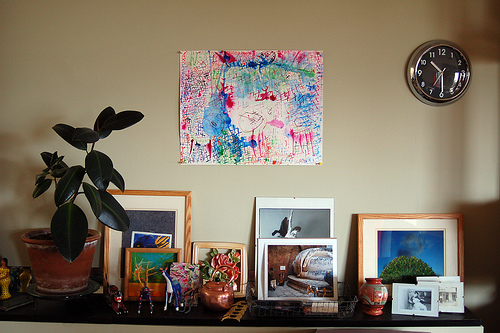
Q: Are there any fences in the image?
A: No, there are no fences.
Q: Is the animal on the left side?
A: Yes, the animal is on the left of the image.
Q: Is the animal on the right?
A: No, the animal is on the left of the image.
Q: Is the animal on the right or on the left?
A: The animal is on the left of the image.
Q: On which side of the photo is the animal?
A: The animal is on the left of the image.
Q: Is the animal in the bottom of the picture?
A: Yes, the animal is in the bottom of the image.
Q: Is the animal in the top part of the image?
A: No, the animal is in the bottom of the image.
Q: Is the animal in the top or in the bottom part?
A: The animal is in the bottom of the image.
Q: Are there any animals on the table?
A: Yes, there is an animal on the table.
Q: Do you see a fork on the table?
A: No, there is an animal on the table.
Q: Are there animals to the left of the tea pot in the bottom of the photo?
A: Yes, there is an animal to the left of the tea pot.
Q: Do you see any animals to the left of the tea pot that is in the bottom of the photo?
A: Yes, there is an animal to the left of the tea pot.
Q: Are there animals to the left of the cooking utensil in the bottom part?
A: Yes, there is an animal to the left of the tea pot.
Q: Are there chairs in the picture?
A: No, there are no chairs.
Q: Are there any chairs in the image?
A: No, there are no chairs.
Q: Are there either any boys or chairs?
A: No, there are no chairs or boys.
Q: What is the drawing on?
A: The drawing is on the wall.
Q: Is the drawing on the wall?
A: Yes, the drawing is on the wall.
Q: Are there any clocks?
A: Yes, there is a clock.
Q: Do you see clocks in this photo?
A: Yes, there is a clock.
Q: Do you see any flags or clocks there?
A: Yes, there is a clock.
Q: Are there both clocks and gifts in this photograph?
A: No, there is a clock but no gifts.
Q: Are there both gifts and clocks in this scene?
A: No, there is a clock but no gifts.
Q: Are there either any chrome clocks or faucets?
A: Yes, there is a chrome clock.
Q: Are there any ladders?
A: No, there are no ladders.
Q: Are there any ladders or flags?
A: No, there are no ladders or flags.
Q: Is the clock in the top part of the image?
A: Yes, the clock is in the top of the image.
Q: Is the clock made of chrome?
A: Yes, the clock is made of chrome.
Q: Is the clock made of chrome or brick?
A: The clock is made of chrome.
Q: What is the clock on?
A: The clock is on the wall.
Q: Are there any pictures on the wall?
A: No, there is a clock on the wall.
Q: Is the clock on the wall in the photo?
A: Yes, the clock is on the wall.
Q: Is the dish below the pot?
A: Yes, the dish is below the pot.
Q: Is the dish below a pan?
A: No, the dish is below the pot.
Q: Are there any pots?
A: Yes, there is a pot.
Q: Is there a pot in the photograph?
A: Yes, there is a pot.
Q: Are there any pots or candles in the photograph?
A: Yes, there is a pot.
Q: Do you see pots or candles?
A: Yes, there is a pot.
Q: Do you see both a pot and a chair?
A: No, there is a pot but no chairs.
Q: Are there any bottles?
A: No, there are no bottles.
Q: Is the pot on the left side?
A: Yes, the pot is on the left of the image.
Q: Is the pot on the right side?
A: No, the pot is on the left of the image.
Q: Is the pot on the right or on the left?
A: The pot is on the left of the image.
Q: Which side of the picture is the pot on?
A: The pot is on the left of the image.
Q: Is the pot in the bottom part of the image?
A: Yes, the pot is in the bottom of the image.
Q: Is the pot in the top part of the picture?
A: No, the pot is in the bottom of the image.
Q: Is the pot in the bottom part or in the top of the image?
A: The pot is in the bottom of the image.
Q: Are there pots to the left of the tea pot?
A: Yes, there is a pot to the left of the tea pot.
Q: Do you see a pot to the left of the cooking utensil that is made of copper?
A: Yes, there is a pot to the left of the tea pot.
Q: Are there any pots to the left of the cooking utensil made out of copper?
A: Yes, there is a pot to the left of the tea pot.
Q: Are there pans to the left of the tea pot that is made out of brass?
A: No, there is a pot to the left of the tea pot.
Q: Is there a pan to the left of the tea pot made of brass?
A: No, there is a pot to the left of the tea pot.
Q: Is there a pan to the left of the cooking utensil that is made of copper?
A: No, there is a pot to the left of the tea pot.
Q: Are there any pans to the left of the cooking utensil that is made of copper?
A: No, there is a pot to the left of the tea pot.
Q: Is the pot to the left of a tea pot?
A: Yes, the pot is to the left of a tea pot.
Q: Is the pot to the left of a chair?
A: No, the pot is to the left of a tea pot.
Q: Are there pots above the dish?
A: Yes, there is a pot above the dish.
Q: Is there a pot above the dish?
A: Yes, there is a pot above the dish.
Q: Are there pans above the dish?
A: No, there is a pot above the dish.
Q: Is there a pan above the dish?
A: No, there is a pot above the dish.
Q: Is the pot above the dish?
A: Yes, the pot is above the dish.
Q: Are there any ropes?
A: No, there are no ropes.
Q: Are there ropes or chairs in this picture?
A: No, there are no ropes or chairs.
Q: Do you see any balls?
A: No, there are no balls.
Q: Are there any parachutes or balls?
A: No, there are no balls or parachutes.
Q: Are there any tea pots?
A: Yes, there is a tea pot.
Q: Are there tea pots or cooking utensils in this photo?
A: Yes, there is a tea pot.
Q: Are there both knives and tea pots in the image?
A: No, there is a tea pot but no knives.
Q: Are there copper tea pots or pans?
A: Yes, there is a copper tea pot.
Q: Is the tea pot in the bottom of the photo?
A: Yes, the tea pot is in the bottom of the image.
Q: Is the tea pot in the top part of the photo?
A: No, the tea pot is in the bottom of the image.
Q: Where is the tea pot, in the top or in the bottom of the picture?
A: The tea pot is in the bottom of the image.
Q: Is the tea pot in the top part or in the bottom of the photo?
A: The tea pot is in the bottom of the image.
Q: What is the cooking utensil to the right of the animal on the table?
A: The cooking utensil is a tea pot.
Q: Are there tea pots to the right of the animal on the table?
A: Yes, there is a tea pot to the right of the animal.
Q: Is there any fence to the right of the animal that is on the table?
A: No, there is a tea pot to the right of the animal.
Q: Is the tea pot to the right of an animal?
A: Yes, the tea pot is to the right of an animal.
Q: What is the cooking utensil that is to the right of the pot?
A: The cooking utensil is a tea pot.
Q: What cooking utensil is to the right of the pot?
A: The cooking utensil is a tea pot.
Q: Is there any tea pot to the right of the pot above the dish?
A: Yes, there is a tea pot to the right of the pot.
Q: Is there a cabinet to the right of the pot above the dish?
A: No, there is a tea pot to the right of the pot.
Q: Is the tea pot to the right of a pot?
A: Yes, the tea pot is to the right of a pot.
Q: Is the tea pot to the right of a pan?
A: No, the tea pot is to the right of a pot.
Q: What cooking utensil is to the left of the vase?
A: The cooking utensil is a tea pot.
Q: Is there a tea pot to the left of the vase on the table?
A: Yes, there is a tea pot to the left of the vase.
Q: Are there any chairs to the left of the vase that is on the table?
A: No, there is a tea pot to the left of the vase.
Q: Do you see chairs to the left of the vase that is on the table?
A: No, there is a tea pot to the left of the vase.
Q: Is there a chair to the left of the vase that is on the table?
A: No, there is a tea pot to the left of the vase.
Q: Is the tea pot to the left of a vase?
A: Yes, the tea pot is to the left of a vase.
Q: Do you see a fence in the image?
A: No, there are no fences.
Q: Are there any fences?
A: No, there are no fences.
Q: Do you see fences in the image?
A: No, there are no fences.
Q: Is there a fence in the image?
A: No, there are no fences.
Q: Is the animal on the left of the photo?
A: Yes, the animal is on the left of the image.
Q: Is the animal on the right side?
A: No, the animal is on the left of the image.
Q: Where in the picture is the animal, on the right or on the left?
A: The animal is on the left of the image.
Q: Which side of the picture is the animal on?
A: The animal is on the left of the image.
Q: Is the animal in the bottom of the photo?
A: Yes, the animal is in the bottom of the image.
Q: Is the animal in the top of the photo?
A: No, the animal is in the bottom of the image.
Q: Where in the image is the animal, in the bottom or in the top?
A: The animal is in the bottom of the image.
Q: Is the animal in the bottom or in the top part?
A: The animal is in the bottom of the image.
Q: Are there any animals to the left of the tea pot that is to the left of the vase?
A: Yes, there is an animal to the left of the tea pot.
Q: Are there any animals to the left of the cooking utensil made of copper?
A: Yes, there is an animal to the left of the tea pot.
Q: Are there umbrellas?
A: No, there are no umbrellas.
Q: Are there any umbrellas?
A: No, there are no umbrellas.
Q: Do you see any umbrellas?
A: No, there are no umbrellas.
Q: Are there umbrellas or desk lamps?
A: No, there are no umbrellas or desk lamps.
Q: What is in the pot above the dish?
A: The plant is in the pot.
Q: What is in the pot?
A: The plant is in the pot.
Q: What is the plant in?
A: The plant is in the pot.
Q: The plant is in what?
A: The plant is in the pot.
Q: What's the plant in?
A: The plant is in the pot.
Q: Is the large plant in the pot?
A: Yes, the plant is in the pot.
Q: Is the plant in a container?
A: No, the plant is in the pot.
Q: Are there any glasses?
A: No, there are no glasses.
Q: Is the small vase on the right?
A: Yes, the vase is on the right of the image.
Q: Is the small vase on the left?
A: No, the vase is on the right of the image.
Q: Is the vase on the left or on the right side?
A: The vase is on the right of the image.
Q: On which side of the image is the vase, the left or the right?
A: The vase is on the right of the image.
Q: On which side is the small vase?
A: The vase is on the right of the image.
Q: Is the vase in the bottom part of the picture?
A: Yes, the vase is in the bottom of the image.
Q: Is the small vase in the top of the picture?
A: No, the vase is in the bottom of the image.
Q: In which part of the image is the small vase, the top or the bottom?
A: The vase is in the bottom of the image.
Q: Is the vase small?
A: Yes, the vase is small.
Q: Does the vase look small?
A: Yes, the vase is small.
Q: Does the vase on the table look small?
A: Yes, the vase is small.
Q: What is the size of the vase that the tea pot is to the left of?
A: The vase is small.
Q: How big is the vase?
A: The vase is small.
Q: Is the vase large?
A: No, the vase is small.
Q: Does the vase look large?
A: No, the vase is small.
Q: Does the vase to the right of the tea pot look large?
A: No, the vase is small.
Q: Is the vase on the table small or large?
A: The vase is small.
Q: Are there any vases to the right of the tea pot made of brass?
A: Yes, there is a vase to the right of the tea pot.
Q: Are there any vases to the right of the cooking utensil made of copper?
A: Yes, there is a vase to the right of the tea pot.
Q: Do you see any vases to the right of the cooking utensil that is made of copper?
A: Yes, there is a vase to the right of the tea pot.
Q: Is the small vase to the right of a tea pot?
A: Yes, the vase is to the right of a tea pot.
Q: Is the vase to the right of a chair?
A: No, the vase is to the right of a tea pot.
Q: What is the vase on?
A: The vase is on the table.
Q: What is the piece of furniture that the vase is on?
A: The piece of furniture is a table.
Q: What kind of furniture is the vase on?
A: The vase is on the table.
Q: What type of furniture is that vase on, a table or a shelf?
A: The vase is on a table.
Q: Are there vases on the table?
A: Yes, there is a vase on the table.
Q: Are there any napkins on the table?
A: No, there is a vase on the table.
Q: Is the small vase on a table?
A: Yes, the vase is on a table.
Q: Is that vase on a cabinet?
A: No, the vase is on a table.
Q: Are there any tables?
A: Yes, there is a table.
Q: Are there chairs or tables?
A: Yes, there is a table.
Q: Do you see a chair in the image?
A: No, there are no chairs.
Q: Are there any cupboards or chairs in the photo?
A: No, there are no chairs or cupboards.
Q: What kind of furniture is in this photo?
A: The furniture is a table.